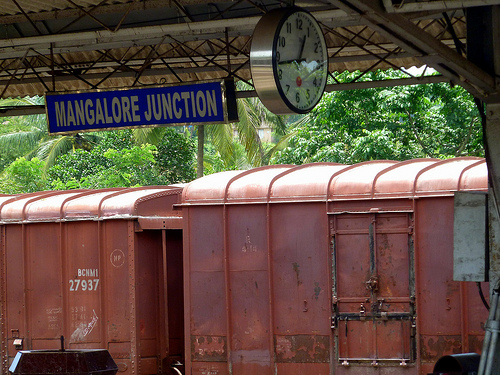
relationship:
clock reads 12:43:
[249, 5, 332, 115] [276, 11, 327, 114]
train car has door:
[2, 163, 497, 373] [325, 208, 420, 369]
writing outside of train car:
[66, 268, 101, 293] [4, 177, 195, 374]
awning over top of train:
[2, 3, 494, 103] [4, 177, 195, 374]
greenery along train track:
[4, 58, 486, 195] [3, 349, 496, 372]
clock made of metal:
[249, 5, 332, 115] [244, 6, 297, 116]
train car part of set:
[2, 163, 497, 373] [3, 153, 495, 371]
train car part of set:
[4, 177, 195, 374] [3, 153, 495, 371]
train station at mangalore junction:
[2, 2, 491, 370] [41, 82, 228, 135]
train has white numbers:
[4, 177, 195, 374] [66, 278, 99, 293]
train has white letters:
[4, 177, 195, 374] [75, 265, 101, 280]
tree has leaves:
[245, 61, 490, 162] [210, 74, 480, 159]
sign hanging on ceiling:
[41, 82, 228, 135] [3, 1, 493, 61]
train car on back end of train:
[4, 177, 195, 374] [3, 153, 495, 371]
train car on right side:
[2, 163, 497, 373] [247, 2, 494, 374]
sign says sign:
[41, 82, 228, 135] [41, 82, 227, 137]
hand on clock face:
[299, 31, 308, 62] [274, 11, 329, 111]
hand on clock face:
[276, 52, 308, 65] [274, 11, 329, 111]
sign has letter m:
[41, 82, 228, 135] [54, 97, 68, 128]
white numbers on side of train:
[66, 278, 99, 293] [4, 177, 195, 374]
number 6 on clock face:
[293, 90, 302, 107] [274, 11, 329, 111]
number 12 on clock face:
[293, 17, 304, 32] [274, 11, 329, 111]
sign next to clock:
[41, 82, 228, 135] [249, 5, 332, 115]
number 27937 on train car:
[66, 278, 99, 293] [4, 177, 195, 374]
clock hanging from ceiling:
[249, 5, 332, 115] [3, 1, 493, 61]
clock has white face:
[249, 5, 332, 115] [274, 11, 329, 111]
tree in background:
[245, 61, 490, 162] [3, 4, 495, 195]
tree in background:
[0, 114, 196, 176] [3, 4, 495, 195]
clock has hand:
[249, 5, 332, 115] [299, 31, 308, 62]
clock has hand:
[249, 5, 332, 115] [276, 52, 308, 65]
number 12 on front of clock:
[293, 17, 304, 32] [249, 5, 332, 115]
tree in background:
[187, 82, 282, 185] [3, 4, 495, 195]